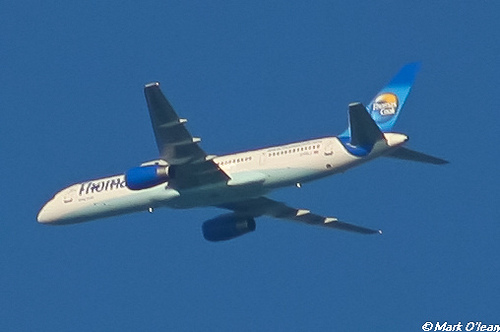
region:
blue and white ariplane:
[30, 52, 458, 243]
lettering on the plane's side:
[77, 175, 134, 198]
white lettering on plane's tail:
[373, 98, 395, 118]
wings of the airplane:
[143, 80, 380, 240]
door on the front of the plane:
[64, 189, 76, 199]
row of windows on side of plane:
[215, 139, 324, 173]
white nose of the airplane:
[31, 211, 47, 223]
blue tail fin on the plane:
[354, 80, 406, 132]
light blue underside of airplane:
[63, 166, 314, 231]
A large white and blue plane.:
[37, 61, 450, 240]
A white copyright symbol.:
[421, 319, 434, 330]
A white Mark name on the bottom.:
[433, 321, 464, 331]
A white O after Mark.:
[463, 319, 474, 330]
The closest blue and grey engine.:
[121, 164, 173, 191]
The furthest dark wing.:
[223, 189, 385, 238]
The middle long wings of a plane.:
[143, 82, 383, 237]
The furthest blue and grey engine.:
[198, 208, 253, 242]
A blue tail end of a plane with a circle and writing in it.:
[342, 57, 425, 135]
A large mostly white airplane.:
[34, 60, 451, 241]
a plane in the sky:
[77, 87, 424, 219]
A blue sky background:
[347, 239, 473, 317]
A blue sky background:
[419, 120, 499, 212]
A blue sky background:
[426, 14, 495, 129]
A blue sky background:
[247, 15, 373, 70]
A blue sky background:
[106, 15, 190, 68]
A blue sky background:
[1, 5, 91, 115]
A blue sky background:
[10, 132, 111, 185]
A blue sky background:
[15, 220, 100, 318]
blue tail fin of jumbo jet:
[336, 55, 424, 167]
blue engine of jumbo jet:
[121, 155, 183, 192]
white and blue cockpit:
[32, 177, 87, 229]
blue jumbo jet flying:
[27, 70, 459, 252]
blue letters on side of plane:
[70, 170, 125, 200]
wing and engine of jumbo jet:
[121, 75, 229, 189]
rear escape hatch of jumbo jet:
[318, 131, 336, 161]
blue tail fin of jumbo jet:
[345, 98, 388, 150]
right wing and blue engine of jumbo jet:
[197, 193, 392, 267]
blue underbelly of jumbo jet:
[171, 170, 268, 204]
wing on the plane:
[138, 80, 223, 179]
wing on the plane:
[253, 185, 383, 247]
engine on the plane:
[120, 149, 175, 196]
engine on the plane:
[200, 201, 261, 248]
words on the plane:
[77, 174, 126, 197]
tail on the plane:
[342, 93, 384, 146]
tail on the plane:
[376, 68, 402, 120]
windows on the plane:
[261, 140, 333, 155]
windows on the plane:
[224, 145, 251, 172]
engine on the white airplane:
[120, 159, 171, 189]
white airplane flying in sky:
[34, 57, 449, 242]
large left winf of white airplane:
[142, 78, 224, 184]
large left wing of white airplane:
[215, 192, 379, 239]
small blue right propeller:
[205, 207, 255, 242]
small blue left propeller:
[124, 160, 174, 190]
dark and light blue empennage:
[344, 47, 429, 134]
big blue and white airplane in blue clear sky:
[34, 59, 448, 244]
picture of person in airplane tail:
[371, 91, 398, 123]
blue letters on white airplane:
[77, 177, 128, 194]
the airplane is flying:
[38, 58, 451, 240]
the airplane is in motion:
[38, 60, 451, 241]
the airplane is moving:
[36, 60, 453, 245]